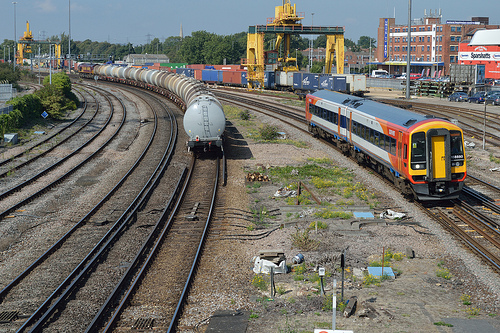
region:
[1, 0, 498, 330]
This is a railroad scene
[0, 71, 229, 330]
These are train tracks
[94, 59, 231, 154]
A line of tanker cars are on the tracks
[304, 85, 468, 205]
This is a passenger train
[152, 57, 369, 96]
These are cargo containers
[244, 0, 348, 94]
A cargo container loader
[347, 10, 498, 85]
Buildings are in the background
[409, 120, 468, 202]
The front of the train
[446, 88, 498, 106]
Cars are parked in the distance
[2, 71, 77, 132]
Vegetation is growing along the tracks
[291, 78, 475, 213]
Red, yellow and grey train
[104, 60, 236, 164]
Round train on tracks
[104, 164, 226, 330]
Metal train tracks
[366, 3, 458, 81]
Large red brick building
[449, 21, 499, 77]
Large red building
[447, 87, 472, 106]
Car parked on street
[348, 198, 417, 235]
Trash in between two train tracks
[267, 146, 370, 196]
Patch of grass between train tracks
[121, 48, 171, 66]
Grey building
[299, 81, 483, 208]
Train on top of train tracks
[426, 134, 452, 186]
yellow door on the train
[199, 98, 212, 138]
ladder on the train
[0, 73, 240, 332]
tracks for the train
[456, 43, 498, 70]
words on a sign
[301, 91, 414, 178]
train is white and red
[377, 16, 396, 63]
blue sign on a building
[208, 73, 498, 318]
tracks for a train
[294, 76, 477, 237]
train on the tracks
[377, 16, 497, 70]
brick building by the trains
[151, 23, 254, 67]
trees by the trains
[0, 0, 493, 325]
a railroad station scene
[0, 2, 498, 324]
two trains running down railroad tracks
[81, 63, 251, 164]
a long grey and brown train coming around a turn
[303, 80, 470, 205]
a short colorful train moving down the tracks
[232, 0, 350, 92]
a yellow and green crane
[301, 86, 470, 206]
a red, grey, and yellow short train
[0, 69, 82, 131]
green bushes growing along the railroad tracks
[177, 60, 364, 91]
colorful freight cars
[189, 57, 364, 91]
white, blue, and red freight cars not attached to trains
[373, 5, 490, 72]
a red brick building with windows on all sides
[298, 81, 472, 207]
a train is on the tracks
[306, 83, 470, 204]
the train is passing by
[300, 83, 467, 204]
the train is making a curve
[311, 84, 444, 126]
the train is grey on top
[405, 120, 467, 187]
the train is yellow in front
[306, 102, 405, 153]
a row of windows are on the side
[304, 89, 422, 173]
the train is painted red and grey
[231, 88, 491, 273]
the tracks are brown and rusted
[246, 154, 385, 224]
patches of grass are on the ground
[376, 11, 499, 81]
a building is in the background